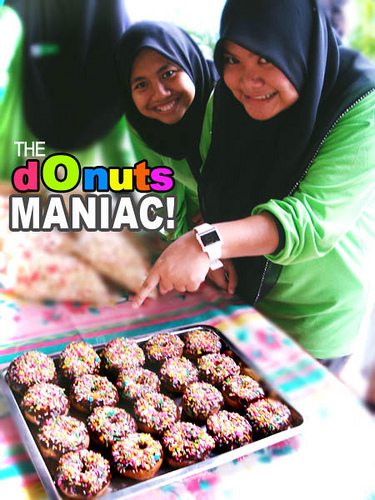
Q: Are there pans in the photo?
A: Yes, there is a pan.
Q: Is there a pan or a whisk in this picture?
A: Yes, there is a pan.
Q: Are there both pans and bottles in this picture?
A: No, there is a pan but no bottles.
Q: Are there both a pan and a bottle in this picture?
A: No, there is a pan but no bottles.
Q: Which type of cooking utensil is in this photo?
A: The cooking utensil is a pan.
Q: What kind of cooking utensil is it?
A: The cooking utensil is a pan.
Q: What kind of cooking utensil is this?
A: This is a pan.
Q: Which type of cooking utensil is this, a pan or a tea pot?
A: This is a pan.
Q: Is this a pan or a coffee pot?
A: This is a pan.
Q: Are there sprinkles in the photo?
A: Yes, there are sprinkles.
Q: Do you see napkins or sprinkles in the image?
A: Yes, there are sprinkles.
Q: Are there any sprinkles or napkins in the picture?
A: Yes, there are sprinkles.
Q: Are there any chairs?
A: No, there are no chairs.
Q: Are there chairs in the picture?
A: No, there are no chairs.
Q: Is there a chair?
A: No, there are no chairs.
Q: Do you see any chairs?
A: No, there are no chairs.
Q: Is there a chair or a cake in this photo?
A: No, there are no chairs or cakes.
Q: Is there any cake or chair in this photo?
A: No, there are no chairs or cakes.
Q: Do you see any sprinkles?
A: Yes, there are sprinkles.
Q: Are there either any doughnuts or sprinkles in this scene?
A: Yes, there are sprinkles.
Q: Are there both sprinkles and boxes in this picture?
A: No, there are sprinkles but no boxes.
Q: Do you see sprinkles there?
A: Yes, there are sprinkles.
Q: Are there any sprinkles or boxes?
A: Yes, there are sprinkles.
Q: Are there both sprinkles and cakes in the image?
A: No, there are sprinkles but no cakes.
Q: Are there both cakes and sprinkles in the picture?
A: No, there are sprinkles but no cakes.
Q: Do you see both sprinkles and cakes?
A: No, there are sprinkles but no cakes.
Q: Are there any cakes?
A: No, there are no cakes.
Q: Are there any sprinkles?
A: Yes, there are sprinkles.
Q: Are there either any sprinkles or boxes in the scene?
A: Yes, there are sprinkles.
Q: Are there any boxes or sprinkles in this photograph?
A: Yes, there are sprinkles.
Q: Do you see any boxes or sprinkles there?
A: Yes, there are sprinkles.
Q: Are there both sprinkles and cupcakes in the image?
A: No, there are sprinkles but no cupcakes.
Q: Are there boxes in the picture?
A: No, there are no boxes.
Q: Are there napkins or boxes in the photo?
A: No, there are no boxes or napkins.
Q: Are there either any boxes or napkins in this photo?
A: No, there are no boxes or napkins.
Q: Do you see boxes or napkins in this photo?
A: No, there are no boxes or napkins.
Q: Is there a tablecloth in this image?
A: Yes, there is a tablecloth.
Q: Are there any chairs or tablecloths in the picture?
A: Yes, there is a tablecloth.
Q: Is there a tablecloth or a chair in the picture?
A: Yes, there is a tablecloth.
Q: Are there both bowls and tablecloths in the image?
A: No, there is a tablecloth but no bowls.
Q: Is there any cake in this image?
A: No, there are no cakes.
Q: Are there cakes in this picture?
A: No, there are no cakes.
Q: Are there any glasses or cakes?
A: No, there are no cakes or glasses.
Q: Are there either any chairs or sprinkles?
A: Yes, there are sprinkles.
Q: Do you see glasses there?
A: No, there are no glasses.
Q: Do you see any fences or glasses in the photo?
A: No, there are no glasses or fences.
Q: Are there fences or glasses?
A: No, there are no glasses or fences.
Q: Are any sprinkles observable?
A: Yes, there are sprinkles.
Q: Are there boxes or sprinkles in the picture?
A: Yes, there are sprinkles.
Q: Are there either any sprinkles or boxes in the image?
A: Yes, there are sprinkles.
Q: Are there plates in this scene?
A: No, there are no plates.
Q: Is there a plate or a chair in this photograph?
A: No, there are no plates or chairs.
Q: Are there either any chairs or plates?
A: No, there are no plates or chairs.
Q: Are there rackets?
A: No, there are no rackets.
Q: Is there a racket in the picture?
A: No, there are no rackets.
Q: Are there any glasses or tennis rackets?
A: No, there are no tennis rackets or glasses.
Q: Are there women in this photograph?
A: Yes, there is a woman.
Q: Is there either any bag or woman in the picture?
A: Yes, there is a woman.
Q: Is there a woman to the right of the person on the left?
A: Yes, there is a woman to the right of the person.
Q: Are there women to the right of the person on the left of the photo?
A: Yes, there is a woman to the right of the person.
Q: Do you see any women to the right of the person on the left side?
A: Yes, there is a woman to the right of the person.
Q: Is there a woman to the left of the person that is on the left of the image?
A: No, the woman is to the right of the person.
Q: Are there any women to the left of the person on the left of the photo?
A: No, the woman is to the right of the person.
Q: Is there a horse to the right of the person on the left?
A: No, there is a woman to the right of the person.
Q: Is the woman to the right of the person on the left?
A: Yes, the woman is to the right of the person.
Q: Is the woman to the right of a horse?
A: No, the woman is to the right of the person.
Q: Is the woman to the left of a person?
A: No, the woman is to the right of a person.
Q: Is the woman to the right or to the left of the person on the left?
A: The woman is to the right of the person.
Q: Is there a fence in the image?
A: No, there are no fences.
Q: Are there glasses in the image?
A: No, there are no glasses.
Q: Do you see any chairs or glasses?
A: No, there are no glasses or chairs.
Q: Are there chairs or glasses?
A: No, there are no chairs or glasses.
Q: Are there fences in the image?
A: No, there are no fences.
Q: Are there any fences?
A: No, there are no fences.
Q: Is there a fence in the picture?
A: No, there are no fences.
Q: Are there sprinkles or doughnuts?
A: Yes, there are sprinkles.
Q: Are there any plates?
A: No, there are no plates.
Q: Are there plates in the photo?
A: No, there are no plates.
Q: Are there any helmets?
A: No, there are no helmets.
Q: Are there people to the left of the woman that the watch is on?
A: Yes, there is a person to the left of the woman.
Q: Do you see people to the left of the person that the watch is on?
A: Yes, there is a person to the left of the woman.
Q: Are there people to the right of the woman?
A: No, the person is to the left of the woman.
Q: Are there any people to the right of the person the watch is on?
A: No, the person is to the left of the woman.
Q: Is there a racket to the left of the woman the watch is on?
A: No, there is a person to the left of the woman.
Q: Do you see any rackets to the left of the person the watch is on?
A: No, there is a person to the left of the woman.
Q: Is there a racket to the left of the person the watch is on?
A: No, there is a person to the left of the woman.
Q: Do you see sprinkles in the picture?
A: Yes, there are sprinkles.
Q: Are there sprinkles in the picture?
A: Yes, there are sprinkles.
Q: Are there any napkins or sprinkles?
A: Yes, there are sprinkles.